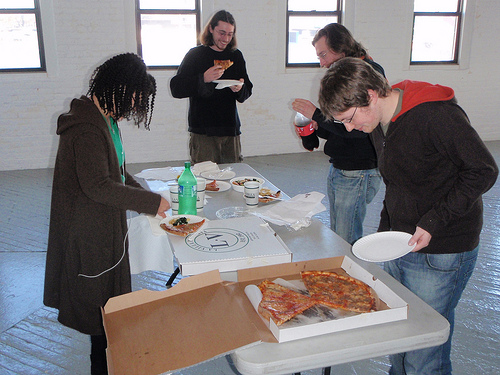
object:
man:
[170, 10, 253, 165]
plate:
[212, 79, 244, 86]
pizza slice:
[213, 59, 234, 71]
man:
[318, 56, 499, 374]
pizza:
[256, 270, 380, 326]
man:
[291, 23, 386, 247]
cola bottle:
[294, 111, 320, 151]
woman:
[43, 52, 171, 374]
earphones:
[78, 117, 132, 279]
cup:
[243, 180, 262, 208]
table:
[140, 162, 450, 374]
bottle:
[177, 161, 198, 216]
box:
[100, 254, 409, 374]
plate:
[159, 214, 208, 237]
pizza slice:
[160, 219, 206, 237]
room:
[1, 1, 500, 375]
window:
[1, 1, 47, 74]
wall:
[0, 0, 499, 172]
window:
[134, 0, 201, 70]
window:
[285, 0, 342, 68]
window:
[410, 0, 464, 65]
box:
[166, 215, 294, 277]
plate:
[351, 230, 417, 263]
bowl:
[230, 175, 266, 193]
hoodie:
[367, 79, 499, 255]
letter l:
[210, 240, 231, 249]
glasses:
[216, 29, 236, 38]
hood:
[375, 79, 458, 138]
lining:
[390, 79, 455, 122]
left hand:
[408, 226, 432, 253]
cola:
[299, 129, 319, 152]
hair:
[199, 10, 236, 50]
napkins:
[249, 191, 326, 232]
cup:
[196, 177, 207, 211]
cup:
[167, 183, 179, 216]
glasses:
[333, 106, 358, 124]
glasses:
[316, 47, 331, 59]